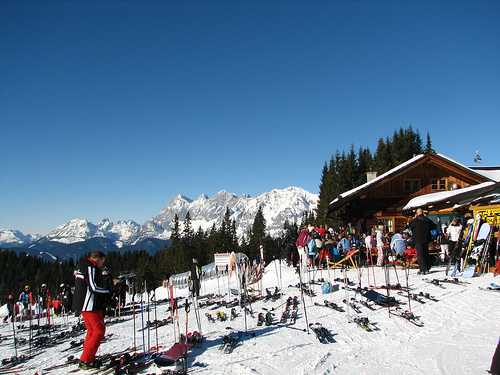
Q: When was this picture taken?
A: Daytime.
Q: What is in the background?
A: Mountains.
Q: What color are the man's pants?
A: Red.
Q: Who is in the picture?
A: A man.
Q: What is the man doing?
A: Skiing.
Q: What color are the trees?
A: Green.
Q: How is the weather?
A: Sunny.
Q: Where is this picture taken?
A: A ski lodge.